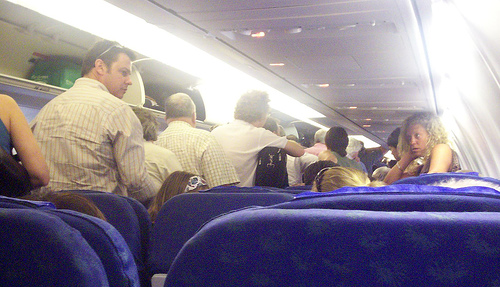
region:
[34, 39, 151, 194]
Man with stripped shirt and glasses on his head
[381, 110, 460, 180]
woman with curly hair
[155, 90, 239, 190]
oler man with checkered shirt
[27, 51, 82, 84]
luggage on an airplane overhead compartment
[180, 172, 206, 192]
headband on a woman's head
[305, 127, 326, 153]
older man in a pink shirt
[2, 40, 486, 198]
people getting off an airplane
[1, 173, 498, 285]
blue seats on an airplane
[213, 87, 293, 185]
person wearing a white shirt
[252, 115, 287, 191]
person wearing black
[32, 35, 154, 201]
a passenger standing in isle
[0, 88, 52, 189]
a passenger standing in isle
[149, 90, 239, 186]
a passenger standing in isle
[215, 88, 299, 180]
a passenger standing in isle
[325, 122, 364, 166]
a passenger standing in isle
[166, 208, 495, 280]
a dark blue seat back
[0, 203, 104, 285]
a dark blue seat back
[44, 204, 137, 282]
a dark blue seat back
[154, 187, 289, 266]
a dark blue seat back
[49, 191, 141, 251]
a dark blue seat back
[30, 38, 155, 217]
person on an airplane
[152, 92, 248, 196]
person on an airplane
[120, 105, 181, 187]
person on an airplane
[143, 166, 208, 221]
person on an airplane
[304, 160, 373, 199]
person on an airplane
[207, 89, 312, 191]
person on an airplane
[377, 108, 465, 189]
person on an airplane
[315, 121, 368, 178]
person on an airplane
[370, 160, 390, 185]
person on an airplane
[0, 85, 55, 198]
person on an airplane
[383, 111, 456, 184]
A woman resting her head on her hand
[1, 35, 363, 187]
Passengers boarding a plane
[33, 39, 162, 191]
Man in a striped short and sunglasses on his head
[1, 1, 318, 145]
Overhead storage compartments on a plane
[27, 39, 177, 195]
A man looking over his shoulder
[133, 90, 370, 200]
The backs of people's heads as they board a plane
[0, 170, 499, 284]
Rows of seats on an airliner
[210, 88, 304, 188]
A man with luggage under his arm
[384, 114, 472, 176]
A woman scratching her head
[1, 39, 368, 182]
Passengers exiting an aircraft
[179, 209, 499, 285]
the top of a purple plane seat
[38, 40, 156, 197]
a man with sunglasses on his head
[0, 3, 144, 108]
above the seat cargo space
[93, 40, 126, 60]
a pair of silver sunglasses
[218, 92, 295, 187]
a man resting his arm on a black bag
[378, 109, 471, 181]
a woman leaning on a seat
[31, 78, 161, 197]
a white long sleeved stripped shirt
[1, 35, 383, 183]
a bunch of people standing in a line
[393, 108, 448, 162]
woman's blonde curly hair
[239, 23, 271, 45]
a passenger seat airplane light that is on